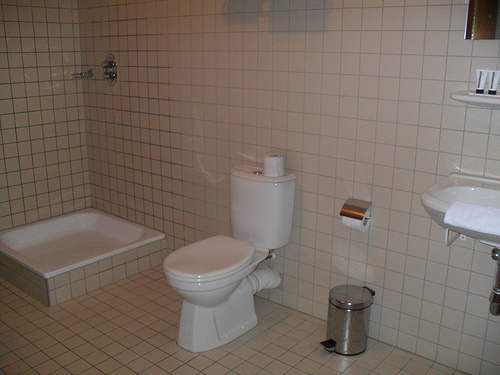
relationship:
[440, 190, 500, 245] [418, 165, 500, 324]
towel hanging on sink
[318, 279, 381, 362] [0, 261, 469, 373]
trash can on floor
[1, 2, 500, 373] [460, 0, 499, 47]
bathroom has mirror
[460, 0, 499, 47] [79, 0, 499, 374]
mirror hanging on wall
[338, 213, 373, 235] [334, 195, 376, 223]
toilet paper in toilet roll holder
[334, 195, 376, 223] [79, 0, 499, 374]
toilet roll holder on wall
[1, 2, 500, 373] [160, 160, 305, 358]
bathroom has toilet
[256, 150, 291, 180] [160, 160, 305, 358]
toilet paper on top of toilet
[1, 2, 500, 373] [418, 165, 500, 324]
bathroom has sink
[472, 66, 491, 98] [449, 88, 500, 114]
bottle on shelf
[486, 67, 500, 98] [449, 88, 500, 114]
bottle on shelf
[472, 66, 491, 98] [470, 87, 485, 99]
bottle has cap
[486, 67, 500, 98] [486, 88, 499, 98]
bottle has cap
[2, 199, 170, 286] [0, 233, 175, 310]
shower base has tiles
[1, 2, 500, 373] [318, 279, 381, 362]
bathroom has trash can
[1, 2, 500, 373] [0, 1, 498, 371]
bathroom has wall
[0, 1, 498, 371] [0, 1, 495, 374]
wall has tile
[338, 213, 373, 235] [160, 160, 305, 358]
toilet paper on top of toilet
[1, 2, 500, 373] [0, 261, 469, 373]
bathroom has floor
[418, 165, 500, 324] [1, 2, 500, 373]
sink in bathroom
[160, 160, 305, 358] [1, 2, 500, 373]
toilet in bathroom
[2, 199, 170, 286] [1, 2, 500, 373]
shower base in bathroom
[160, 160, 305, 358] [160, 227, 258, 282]
toilet has lid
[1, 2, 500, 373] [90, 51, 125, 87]
bathroom has shower mechanism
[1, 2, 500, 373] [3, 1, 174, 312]
bathroom has shower stall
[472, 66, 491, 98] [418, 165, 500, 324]
bottle by sink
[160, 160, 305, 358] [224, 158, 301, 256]
toilet has tank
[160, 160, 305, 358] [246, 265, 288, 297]
toilet has pipe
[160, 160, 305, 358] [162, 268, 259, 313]
toilet has bowl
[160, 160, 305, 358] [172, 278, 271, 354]
toilet has base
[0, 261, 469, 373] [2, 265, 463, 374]
floor has tile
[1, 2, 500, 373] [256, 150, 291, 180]
bathroom has toilet paper